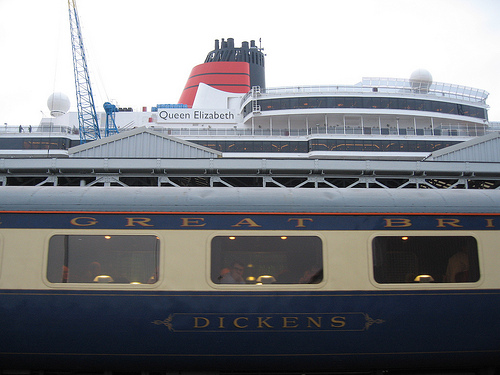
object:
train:
[7, 189, 494, 373]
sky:
[88, 0, 197, 110]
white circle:
[47, 93, 72, 118]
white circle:
[409, 70, 433, 93]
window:
[45, 233, 160, 284]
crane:
[67, 0, 119, 145]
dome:
[47, 91, 70, 117]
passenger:
[219, 260, 246, 284]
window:
[209, 234, 324, 285]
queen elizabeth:
[158, 110, 234, 120]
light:
[104, 235, 112, 240]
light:
[229, 236, 236, 241]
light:
[280, 235, 288, 240]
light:
[401, 236, 408, 241]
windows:
[370, 235, 481, 285]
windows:
[202, 230, 328, 288]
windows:
[259, 95, 329, 111]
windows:
[365, 96, 418, 110]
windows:
[261, 99, 440, 138]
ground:
[414, 162, 471, 204]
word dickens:
[194, 316, 345, 328]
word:
[69, 217, 313, 227]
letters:
[70, 216, 314, 227]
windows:
[45, 233, 481, 285]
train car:
[4, 184, 496, 360]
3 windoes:
[47, 233, 162, 284]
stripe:
[4, 158, 499, 170]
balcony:
[249, 93, 491, 136]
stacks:
[204, 37, 267, 65]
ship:
[5, 37, 484, 369]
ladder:
[65, 0, 100, 144]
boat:
[4, 28, 498, 372]